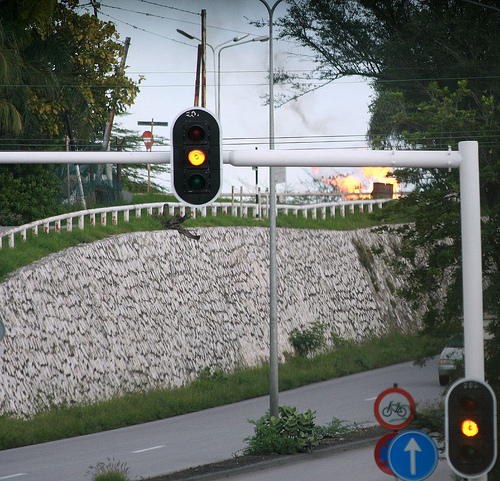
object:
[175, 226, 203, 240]
tomato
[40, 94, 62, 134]
flowers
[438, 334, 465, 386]
front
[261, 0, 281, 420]
gray pole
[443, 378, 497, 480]
stop light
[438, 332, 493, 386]
car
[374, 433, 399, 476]
sign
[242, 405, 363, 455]
bush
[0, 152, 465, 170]
pole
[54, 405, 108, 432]
grass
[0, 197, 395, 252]
guard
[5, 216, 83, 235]
fence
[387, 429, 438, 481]
sign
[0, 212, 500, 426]
wall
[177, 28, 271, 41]
street lights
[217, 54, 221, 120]
pole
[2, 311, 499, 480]
road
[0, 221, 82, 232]
road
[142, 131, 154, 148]
sign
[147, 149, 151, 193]
pole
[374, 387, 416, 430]
sign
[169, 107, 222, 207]
light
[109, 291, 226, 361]
rock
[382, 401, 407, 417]
bicycle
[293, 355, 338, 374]
grass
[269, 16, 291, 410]
pole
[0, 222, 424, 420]
brick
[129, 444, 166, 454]
lines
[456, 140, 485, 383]
pole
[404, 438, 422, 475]
arrow